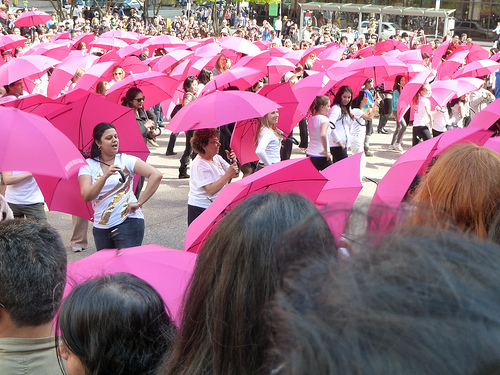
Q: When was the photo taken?
A: Daytime.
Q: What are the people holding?
A: Umbrellas.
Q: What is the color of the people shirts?
A: White.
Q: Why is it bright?
A: Sunny.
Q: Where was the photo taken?
A: In a large courtyard where there is a performance.